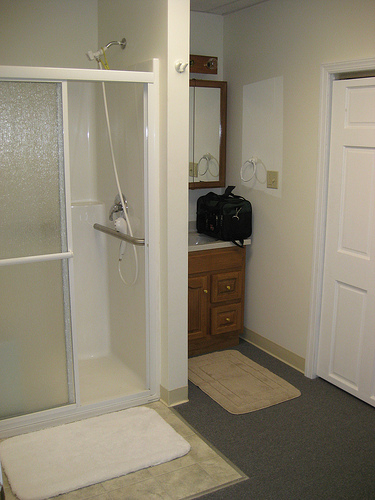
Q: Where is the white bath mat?
A: On the floor.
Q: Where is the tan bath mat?
A: On the floor.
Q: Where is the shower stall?
A: In front of the bath mat.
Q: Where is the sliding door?
A: On the shower.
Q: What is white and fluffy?
A: The bath mat.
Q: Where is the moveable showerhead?
A: In the shower.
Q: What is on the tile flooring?
A: A bath mat.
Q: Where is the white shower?
A: In the bathroom.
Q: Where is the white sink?
A: Under the mirror.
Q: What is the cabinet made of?
A: Medium brown wood.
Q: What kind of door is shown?
A: A white six panel door.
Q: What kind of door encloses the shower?
A: Frosted glass.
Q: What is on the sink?
A: A black bag.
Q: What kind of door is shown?
A: A white six panel door.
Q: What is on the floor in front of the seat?
A: A rug.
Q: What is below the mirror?
A: A sink.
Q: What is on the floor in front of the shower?
A: A white rug.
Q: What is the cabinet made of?
A: Wood.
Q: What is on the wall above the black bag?
A: A round towel holder.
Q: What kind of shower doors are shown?
A: Sliding glass shower doors.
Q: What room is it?
A: Bathroom.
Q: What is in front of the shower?
A: White bathroom rug.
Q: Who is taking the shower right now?
A: Nobody.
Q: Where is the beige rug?
A: On the floor by the sink.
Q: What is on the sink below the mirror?
A: A large black bag.